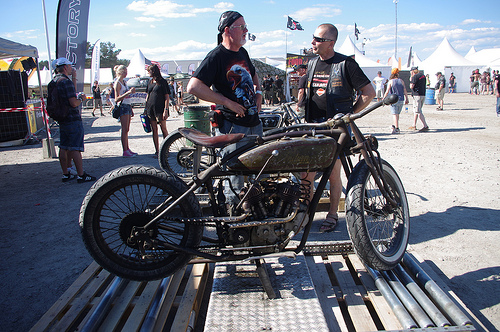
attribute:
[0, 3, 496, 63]
sky — blue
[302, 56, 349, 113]
vest — black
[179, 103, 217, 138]
trash can — green, painted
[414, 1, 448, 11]
sky — blue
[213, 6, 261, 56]
man — light skinned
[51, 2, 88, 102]
banner — large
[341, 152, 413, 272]
front tire — black, rubber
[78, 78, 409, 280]
motorcycle — black, antique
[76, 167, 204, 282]
tire — rubber, black, rear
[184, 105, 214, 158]
drum — green, metal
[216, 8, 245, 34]
bandana — black